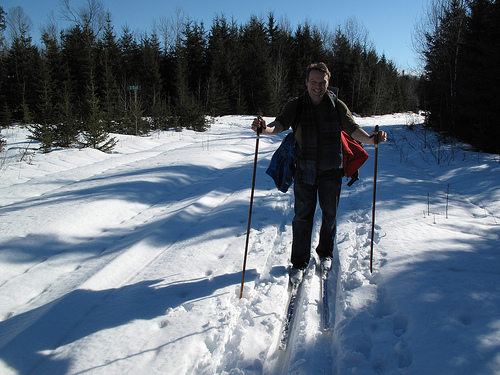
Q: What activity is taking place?
A: Cross-country skiing.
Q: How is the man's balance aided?
A: Ski poles.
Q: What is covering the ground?
A: Snow.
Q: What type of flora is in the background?
A: Trees.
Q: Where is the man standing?
A: On skies.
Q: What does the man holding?
A: Ski poles.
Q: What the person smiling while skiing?
A: Yes.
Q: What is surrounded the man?
A: Snow.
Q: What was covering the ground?
A: Snow.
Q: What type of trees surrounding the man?
A: Pine Trees.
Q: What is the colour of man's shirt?
A: Black.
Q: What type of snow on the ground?
A: Fluffy Snow.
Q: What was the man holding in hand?
A: Ski pole.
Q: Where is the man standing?
A: In the snow.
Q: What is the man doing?
A: Skiing.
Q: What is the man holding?
A: Ski poles.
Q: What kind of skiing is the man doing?
A: Cross country.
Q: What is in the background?
A: Trees.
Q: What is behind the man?
A: Tracks.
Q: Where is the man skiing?
A: Snowy road.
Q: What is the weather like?
A: Clear.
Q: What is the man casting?
A: Shadow.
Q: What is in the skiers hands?
A: Ski poles.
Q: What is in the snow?
A: Ski tracks.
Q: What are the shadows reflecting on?
A: Snow.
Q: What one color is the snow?
A: White.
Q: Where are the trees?
A: Behind the ski trail.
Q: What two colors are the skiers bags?
A: Blue and red.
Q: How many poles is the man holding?
A: Two.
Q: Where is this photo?
A: Nature.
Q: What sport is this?
A: Cross country skiing.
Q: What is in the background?
A: Trees.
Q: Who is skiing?
A: Man.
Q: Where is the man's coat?
A: On his back.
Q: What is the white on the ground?
A: Snow.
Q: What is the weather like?
A: Sunny.